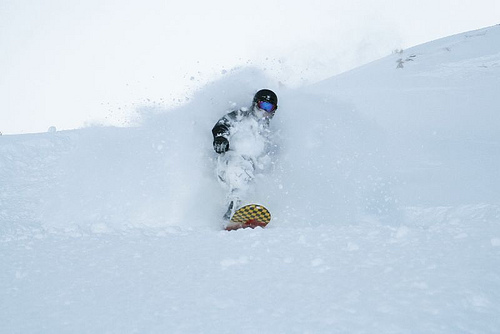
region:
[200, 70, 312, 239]
snowboarder buried in snow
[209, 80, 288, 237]
snowboarder covered in snow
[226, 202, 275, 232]
checkered bottom of snowboard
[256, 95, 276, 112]
snowboarders blurry goggles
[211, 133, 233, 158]
snowboarder's hand wearing a glove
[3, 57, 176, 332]
area of white snow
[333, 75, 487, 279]
area of white snow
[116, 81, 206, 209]
snow flung out due to snowboarder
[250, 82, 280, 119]
head of the snowboarder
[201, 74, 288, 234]
snowboarder in a weird pose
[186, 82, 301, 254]
this is a man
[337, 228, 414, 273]
this is snow on the ground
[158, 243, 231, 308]
this is snow on the ground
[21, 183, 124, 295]
this is snow on the ground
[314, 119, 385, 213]
this is snow on the ground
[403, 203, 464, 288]
this is snow on the ground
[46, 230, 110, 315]
this is snow on the ground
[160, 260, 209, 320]
this is snow on the ground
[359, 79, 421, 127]
this is snow on the ground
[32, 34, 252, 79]
the sky is clear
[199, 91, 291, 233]
a snowboarder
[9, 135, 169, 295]
the snow is white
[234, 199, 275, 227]
a snowboard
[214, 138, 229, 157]
person is wearing gloves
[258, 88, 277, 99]
person is wearing a helmet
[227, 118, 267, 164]
the person is covered in snow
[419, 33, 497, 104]
a mountain of snow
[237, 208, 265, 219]
the bottom of the snowboard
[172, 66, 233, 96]
snow particles in the air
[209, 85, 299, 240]
young man snow boading on hill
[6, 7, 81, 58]
blue sky with no clouds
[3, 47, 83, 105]
blue sky with no clouds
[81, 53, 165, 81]
blue sky with no clouds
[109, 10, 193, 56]
blue sky with no clouds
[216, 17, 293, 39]
blue sky with no clouds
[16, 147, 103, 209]
white snow on hill side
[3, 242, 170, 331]
white snow on hill side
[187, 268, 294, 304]
white snow on hill side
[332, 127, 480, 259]
white snow on hill side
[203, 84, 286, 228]
Snowboarder on the slope.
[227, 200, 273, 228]
Black checkered snowboard on slope.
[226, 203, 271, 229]
Yellow checkered board on the slope.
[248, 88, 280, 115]
Black helmet on snowboarder.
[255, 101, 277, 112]
Blue goggles on snowboarder.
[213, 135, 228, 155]
Black gloves on snowboarder.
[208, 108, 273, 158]
Black jacket on snowboarder.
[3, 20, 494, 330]
Lots of snow on the slopes.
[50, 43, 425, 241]
Snow being kicked up by board.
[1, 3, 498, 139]
Cloudy skies in the background.